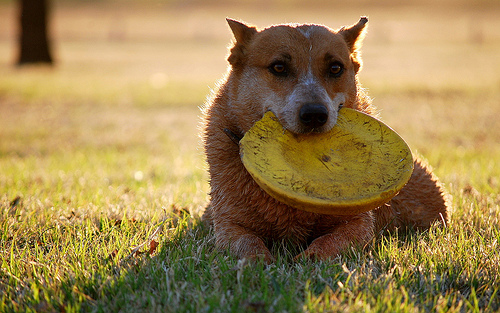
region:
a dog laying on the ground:
[185, 12, 445, 275]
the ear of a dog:
[222, 12, 255, 72]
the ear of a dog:
[337, 10, 374, 62]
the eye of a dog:
[264, 55, 298, 83]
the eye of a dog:
[322, 52, 346, 85]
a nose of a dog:
[294, 97, 330, 133]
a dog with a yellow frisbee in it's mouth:
[217, 4, 423, 211]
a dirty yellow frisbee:
[234, 109, 429, 215]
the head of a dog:
[214, 8, 388, 148]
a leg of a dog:
[207, 218, 277, 267]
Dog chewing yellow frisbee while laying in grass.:
[203, 17, 450, 262]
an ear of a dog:
[336, 12, 372, 53]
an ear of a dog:
[221, 17, 248, 71]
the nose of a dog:
[292, 97, 335, 132]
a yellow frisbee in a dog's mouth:
[229, 85, 428, 212]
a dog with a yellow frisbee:
[210, 13, 425, 225]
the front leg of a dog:
[294, 207, 381, 272]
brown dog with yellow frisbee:
[205, 22, 432, 236]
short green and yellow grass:
[75, 189, 119, 207]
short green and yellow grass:
[394, 253, 458, 304]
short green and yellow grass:
[304, 261, 391, 311]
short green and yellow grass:
[228, 248, 279, 306]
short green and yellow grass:
[128, 246, 193, 280]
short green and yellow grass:
[84, 183, 185, 240]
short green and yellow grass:
[94, 266, 158, 307]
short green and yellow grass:
[444, 88, 479, 133]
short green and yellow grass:
[394, 66, 462, 123]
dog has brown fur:
[200, 24, 420, 243]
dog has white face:
[271, 29, 333, 146]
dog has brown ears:
[215, 12, 370, 54]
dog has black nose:
[229, 94, 351, 149]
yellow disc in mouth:
[228, 115, 412, 205]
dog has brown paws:
[203, 203, 377, 274]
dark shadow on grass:
[141, 224, 346, 304]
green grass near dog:
[49, 167, 113, 309]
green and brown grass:
[75, 76, 177, 198]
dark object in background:
[3, 7, 83, 59]